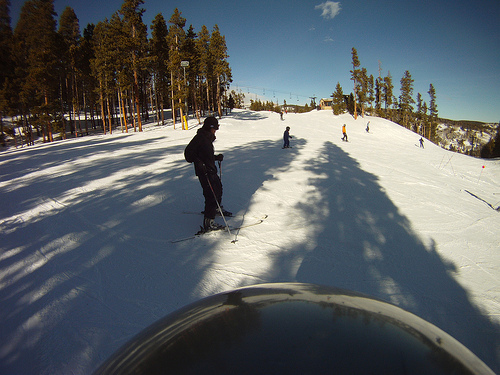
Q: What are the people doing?
A: Skiing.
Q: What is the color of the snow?
A: White.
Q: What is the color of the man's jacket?
A: Black.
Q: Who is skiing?
A: The people.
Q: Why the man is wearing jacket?
A: It's winter.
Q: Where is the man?
A: On the slope.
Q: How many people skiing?
A: Six.